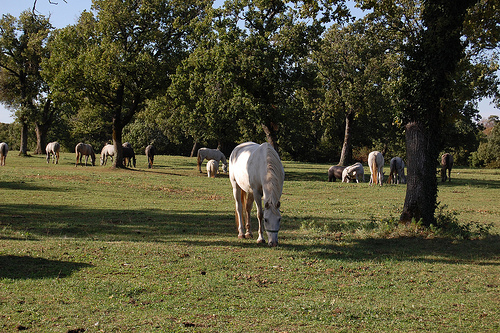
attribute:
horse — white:
[220, 142, 284, 242]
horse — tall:
[41, 140, 61, 165]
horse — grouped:
[187, 146, 229, 176]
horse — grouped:
[360, 145, 397, 182]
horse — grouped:
[33, 130, 65, 163]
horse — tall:
[217, 138, 291, 250]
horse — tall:
[323, 147, 468, 185]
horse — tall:
[190, 142, 227, 176]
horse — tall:
[0, 131, 165, 167]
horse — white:
[364, 147, 384, 183]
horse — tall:
[193, 144, 233, 181]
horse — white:
[231, 142, 284, 244]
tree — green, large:
[57, 37, 142, 128]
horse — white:
[222, 134, 290, 248]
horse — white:
[226, 115, 299, 237]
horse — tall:
[147, 138, 159, 169]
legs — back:
[232, 187, 252, 241]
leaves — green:
[68, 41, 124, 87]